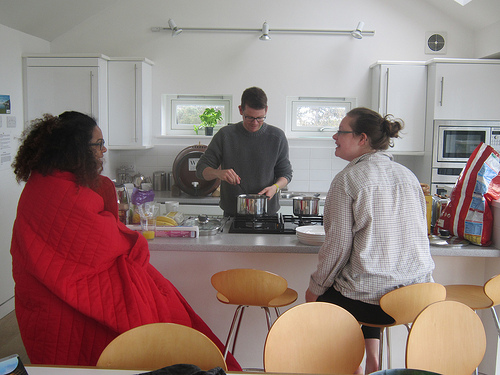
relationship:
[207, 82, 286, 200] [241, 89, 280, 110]
man has hair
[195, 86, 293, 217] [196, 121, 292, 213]
man wearing shirt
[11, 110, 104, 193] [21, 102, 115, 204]
curly hair on woman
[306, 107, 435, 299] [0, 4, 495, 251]
person sitting in kitchen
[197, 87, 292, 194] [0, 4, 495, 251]
person sitting in kitchen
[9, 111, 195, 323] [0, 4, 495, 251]
person sitting in kitchen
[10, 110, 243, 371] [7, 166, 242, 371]
person wearing blanket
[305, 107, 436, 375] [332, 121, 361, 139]
person wearing glasses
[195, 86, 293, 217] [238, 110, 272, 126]
man wearing glasses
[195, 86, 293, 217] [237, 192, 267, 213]
man stirring pot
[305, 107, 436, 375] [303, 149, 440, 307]
person wearing plaid shirt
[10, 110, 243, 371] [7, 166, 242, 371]
person wrapped in blanket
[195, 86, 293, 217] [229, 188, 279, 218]
man stirring pot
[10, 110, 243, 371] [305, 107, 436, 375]
person smiling at person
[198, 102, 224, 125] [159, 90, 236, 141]
plant behind windowsill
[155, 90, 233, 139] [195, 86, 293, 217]
window behind man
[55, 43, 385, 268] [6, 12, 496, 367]
picture in home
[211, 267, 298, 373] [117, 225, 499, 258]
stool in front of counter top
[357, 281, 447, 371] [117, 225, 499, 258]
stool in front of counter top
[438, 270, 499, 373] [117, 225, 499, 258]
stool in front of counter top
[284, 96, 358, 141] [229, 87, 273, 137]
window behind head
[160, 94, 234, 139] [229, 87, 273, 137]
window behind head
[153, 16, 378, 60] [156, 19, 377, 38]
lights on track